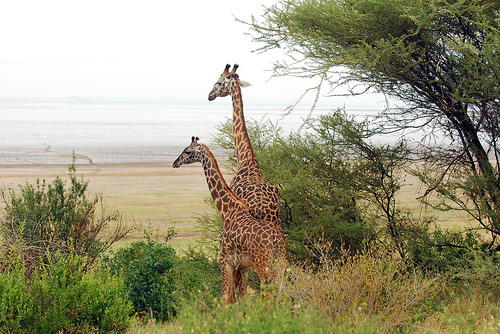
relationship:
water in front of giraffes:
[115, 97, 180, 137] [173, 62, 288, 306]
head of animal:
[162, 126, 228, 185] [204, 11, 321, 245]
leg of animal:
[219, 265, 232, 306] [176, 135, 286, 302]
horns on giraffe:
[186, 134, 198, 144] [167, 134, 289, 298]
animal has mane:
[173, 135, 286, 306] [202, 143, 250, 210]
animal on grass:
[173, 135, 274, 304] [127, 253, 498, 332]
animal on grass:
[209, 63, 280, 223] [127, 253, 498, 332]